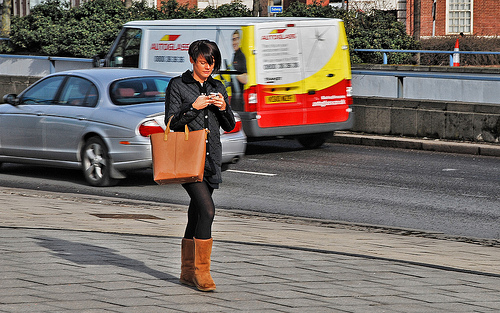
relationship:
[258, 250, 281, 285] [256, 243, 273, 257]
part of a floor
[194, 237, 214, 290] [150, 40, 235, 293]
boot of lady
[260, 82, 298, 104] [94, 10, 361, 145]
license plate mounted on van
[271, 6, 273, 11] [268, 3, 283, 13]
letter painted on sign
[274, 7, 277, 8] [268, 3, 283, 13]
letter painted on sign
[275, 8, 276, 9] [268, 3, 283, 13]
letter painted on sign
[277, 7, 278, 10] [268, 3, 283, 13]
letter painted on sign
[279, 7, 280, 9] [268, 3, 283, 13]
letter painted on sign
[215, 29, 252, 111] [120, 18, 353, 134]
picture painted on white van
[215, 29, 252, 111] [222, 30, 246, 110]
picture depicting man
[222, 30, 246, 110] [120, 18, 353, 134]
man painted on white van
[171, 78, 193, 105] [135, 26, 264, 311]
coat on a lady